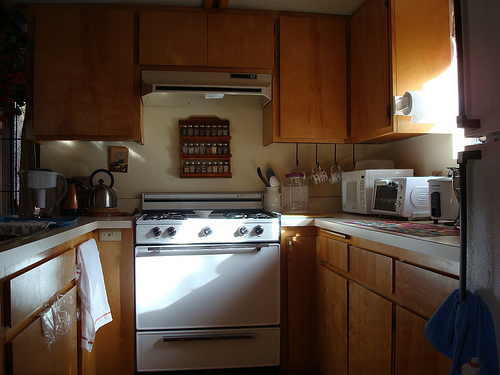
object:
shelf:
[177, 156, 232, 179]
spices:
[181, 161, 191, 176]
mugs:
[304, 163, 329, 185]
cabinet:
[263, 10, 347, 150]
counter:
[0, 207, 460, 264]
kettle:
[73, 168, 118, 209]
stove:
[134, 188, 281, 373]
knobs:
[150, 226, 160, 236]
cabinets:
[311, 218, 463, 372]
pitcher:
[20, 167, 61, 211]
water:
[22, 206, 52, 218]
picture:
[106, 146, 130, 174]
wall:
[41, 103, 392, 209]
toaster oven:
[370, 175, 445, 221]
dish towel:
[73, 238, 115, 353]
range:
[139, 70, 273, 109]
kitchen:
[0, 1, 499, 374]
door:
[134, 242, 283, 329]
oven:
[131, 244, 281, 331]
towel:
[420, 287, 497, 374]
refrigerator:
[449, 0, 499, 375]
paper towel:
[401, 90, 439, 122]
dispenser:
[390, 92, 410, 117]